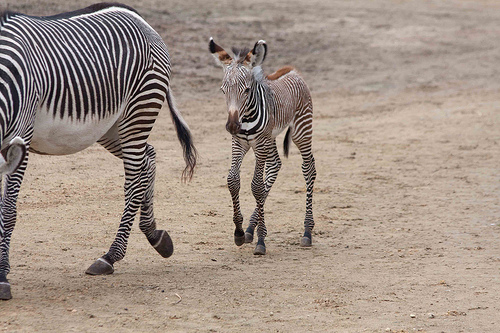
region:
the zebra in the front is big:
[0, 1, 202, 307]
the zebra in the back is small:
[195, 23, 325, 260]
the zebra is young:
[202, 31, 327, 258]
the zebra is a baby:
[201, 30, 328, 261]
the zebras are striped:
[2, 0, 323, 300]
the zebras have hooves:
[0, 215, 322, 308]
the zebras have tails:
[158, 52, 304, 189]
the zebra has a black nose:
[220, 103, 244, 135]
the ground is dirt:
[0, 0, 499, 332]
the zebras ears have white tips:
[203, 31, 273, 59]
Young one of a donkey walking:
[202, 36, 322, 252]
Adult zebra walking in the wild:
[0, 5, 191, 295]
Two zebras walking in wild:
[0, 11, 326, 301]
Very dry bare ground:
[318, 15, 498, 326]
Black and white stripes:
[53, 5, 159, 112]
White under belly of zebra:
[32, 113, 119, 154]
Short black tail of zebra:
[167, 96, 197, 182]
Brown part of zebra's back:
[260, 63, 300, 78]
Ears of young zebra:
[205, 35, 270, 70]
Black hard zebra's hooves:
[83, 230, 195, 280]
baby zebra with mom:
[195, 21, 339, 272]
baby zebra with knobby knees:
[206, 30, 334, 291]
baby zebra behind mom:
[198, 28, 348, 263]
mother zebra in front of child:
[3, 7, 213, 303]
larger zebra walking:
[8, 7, 219, 276]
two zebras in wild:
[8, 12, 349, 286]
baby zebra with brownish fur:
[196, 29, 363, 277]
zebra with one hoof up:
[6, 199, 196, 279]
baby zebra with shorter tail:
[204, 35, 337, 259]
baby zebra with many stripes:
[201, 48, 352, 261]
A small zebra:
[180, 16, 375, 288]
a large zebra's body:
[3, 5, 200, 291]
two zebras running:
[7, 4, 413, 287]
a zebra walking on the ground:
[209, 24, 393, 288]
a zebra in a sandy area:
[203, 26, 473, 304]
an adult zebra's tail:
[145, 45, 208, 179]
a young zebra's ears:
[200, 32, 280, 80]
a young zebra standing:
[187, 17, 381, 270]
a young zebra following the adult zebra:
[22, 7, 384, 321]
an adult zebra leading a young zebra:
[10, 7, 375, 279]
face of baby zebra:
[178, 61, 272, 141]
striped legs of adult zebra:
[97, 146, 186, 243]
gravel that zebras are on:
[320, 242, 430, 297]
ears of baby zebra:
[194, 40, 290, 89]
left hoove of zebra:
[77, 255, 182, 282]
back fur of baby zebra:
[265, 68, 310, 82]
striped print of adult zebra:
[17, 49, 111, 121]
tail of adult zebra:
[145, 97, 217, 159]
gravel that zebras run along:
[357, 76, 437, 216]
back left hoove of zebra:
[295, 234, 322, 261]